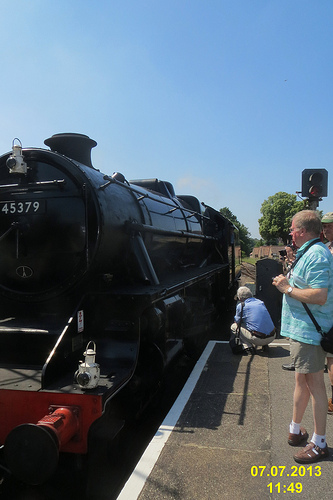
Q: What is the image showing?
A: It is showing a station.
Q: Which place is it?
A: It is a station.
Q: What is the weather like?
A: It is clear.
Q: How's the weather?
A: It is clear.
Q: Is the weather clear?
A: Yes, it is clear.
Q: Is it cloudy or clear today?
A: It is clear.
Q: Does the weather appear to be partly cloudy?
A: No, it is clear.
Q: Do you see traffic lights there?
A: Yes, there is a traffic light.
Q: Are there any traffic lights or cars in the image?
A: Yes, there is a traffic light.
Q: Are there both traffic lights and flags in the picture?
A: No, there is a traffic light but no flags.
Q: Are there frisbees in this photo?
A: No, there are no frisbees.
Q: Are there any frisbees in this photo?
A: No, there are no frisbees.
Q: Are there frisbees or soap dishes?
A: No, there are no frisbees or soap dishes.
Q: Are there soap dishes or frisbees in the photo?
A: No, there are no frisbees or soap dishes.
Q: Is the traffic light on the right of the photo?
A: Yes, the traffic light is on the right of the image.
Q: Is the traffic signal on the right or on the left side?
A: The traffic signal is on the right of the image.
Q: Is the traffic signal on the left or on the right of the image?
A: The traffic signal is on the right of the image.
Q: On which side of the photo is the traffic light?
A: The traffic light is on the right of the image.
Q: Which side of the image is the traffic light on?
A: The traffic light is on the right of the image.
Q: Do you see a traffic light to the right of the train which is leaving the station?
A: Yes, there is a traffic light to the right of the train.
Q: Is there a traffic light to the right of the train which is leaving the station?
A: Yes, there is a traffic light to the right of the train.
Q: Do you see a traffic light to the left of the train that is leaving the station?
A: No, the traffic light is to the right of the train.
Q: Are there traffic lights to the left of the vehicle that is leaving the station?
A: No, the traffic light is to the right of the train.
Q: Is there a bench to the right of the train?
A: No, there is a traffic light to the right of the train.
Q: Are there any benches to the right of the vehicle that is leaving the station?
A: No, there is a traffic light to the right of the train.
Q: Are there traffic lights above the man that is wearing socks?
A: Yes, there is a traffic light above the man.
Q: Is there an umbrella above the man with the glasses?
A: No, there is a traffic light above the man.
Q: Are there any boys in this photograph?
A: No, there are no boys.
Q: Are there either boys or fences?
A: No, there are no boys or fences.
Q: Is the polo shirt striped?
A: Yes, the polo shirt is striped.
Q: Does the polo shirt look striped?
A: Yes, the polo shirt is striped.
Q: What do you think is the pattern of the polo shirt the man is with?
A: The polo shirt is striped.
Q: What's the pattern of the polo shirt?
A: The polo shirt is striped.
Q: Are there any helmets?
A: No, there are no helmets.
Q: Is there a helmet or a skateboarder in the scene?
A: No, there are no helmets or skateboarders.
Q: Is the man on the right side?
A: Yes, the man is on the right of the image.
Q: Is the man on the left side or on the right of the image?
A: The man is on the right of the image.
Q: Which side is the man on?
A: The man is on the right of the image.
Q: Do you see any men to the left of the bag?
A: Yes, there is a man to the left of the bag.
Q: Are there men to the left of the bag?
A: Yes, there is a man to the left of the bag.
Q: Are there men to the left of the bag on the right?
A: Yes, there is a man to the left of the bag.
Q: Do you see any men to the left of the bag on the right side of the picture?
A: Yes, there is a man to the left of the bag.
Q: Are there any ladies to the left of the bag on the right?
A: No, there is a man to the left of the bag.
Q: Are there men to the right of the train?
A: Yes, there is a man to the right of the train.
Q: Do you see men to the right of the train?
A: Yes, there is a man to the right of the train.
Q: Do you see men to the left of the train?
A: No, the man is to the right of the train.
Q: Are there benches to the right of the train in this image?
A: No, there is a man to the right of the train.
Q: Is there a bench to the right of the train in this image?
A: No, there is a man to the right of the train.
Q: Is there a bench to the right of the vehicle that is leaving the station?
A: No, there is a man to the right of the train.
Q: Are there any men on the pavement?
A: Yes, there is a man on the pavement.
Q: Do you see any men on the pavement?
A: Yes, there is a man on the pavement.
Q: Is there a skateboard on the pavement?
A: No, there is a man on the pavement.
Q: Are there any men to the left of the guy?
A: Yes, there is a man to the left of the guy.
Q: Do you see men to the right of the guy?
A: No, the man is to the left of the guy.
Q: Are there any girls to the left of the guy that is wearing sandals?
A: No, there is a man to the left of the guy.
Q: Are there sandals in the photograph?
A: Yes, there are sandals.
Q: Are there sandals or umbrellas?
A: Yes, there are sandals.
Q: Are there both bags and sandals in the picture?
A: Yes, there are both sandals and a bag.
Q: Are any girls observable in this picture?
A: No, there are no girls.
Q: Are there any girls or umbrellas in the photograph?
A: No, there are no girls or umbrellas.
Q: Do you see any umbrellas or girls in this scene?
A: No, there are no girls or umbrellas.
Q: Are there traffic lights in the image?
A: Yes, there is a traffic light.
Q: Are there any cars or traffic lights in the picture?
A: Yes, there is a traffic light.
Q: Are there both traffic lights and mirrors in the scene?
A: No, there is a traffic light but no mirrors.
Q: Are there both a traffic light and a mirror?
A: No, there is a traffic light but no mirrors.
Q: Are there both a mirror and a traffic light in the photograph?
A: No, there is a traffic light but no mirrors.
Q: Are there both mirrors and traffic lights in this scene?
A: No, there is a traffic light but no mirrors.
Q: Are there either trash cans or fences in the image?
A: No, there are no fences or trash cans.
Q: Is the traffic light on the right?
A: Yes, the traffic light is on the right of the image.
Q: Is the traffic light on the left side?
A: No, the traffic light is on the right of the image.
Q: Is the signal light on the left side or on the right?
A: The signal light is on the right of the image.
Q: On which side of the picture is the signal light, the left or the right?
A: The signal light is on the right of the image.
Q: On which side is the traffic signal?
A: The traffic signal is on the right of the image.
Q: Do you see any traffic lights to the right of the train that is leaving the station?
A: Yes, there is a traffic light to the right of the train.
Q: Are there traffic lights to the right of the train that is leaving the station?
A: Yes, there is a traffic light to the right of the train.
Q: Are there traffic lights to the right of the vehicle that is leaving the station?
A: Yes, there is a traffic light to the right of the train.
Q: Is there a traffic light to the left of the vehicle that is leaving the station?
A: No, the traffic light is to the right of the train.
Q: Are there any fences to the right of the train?
A: No, there is a traffic light to the right of the train.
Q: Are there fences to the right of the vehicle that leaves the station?
A: No, there is a traffic light to the right of the train.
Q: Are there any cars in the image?
A: No, there are no cars.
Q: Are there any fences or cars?
A: No, there are no cars or fences.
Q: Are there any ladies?
A: No, there are no ladies.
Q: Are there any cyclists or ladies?
A: No, there are no ladies or cyclists.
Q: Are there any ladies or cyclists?
A: No, there are no ladies or cyclists.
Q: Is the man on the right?
A: Yes, the man is on the right of the image.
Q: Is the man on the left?
A: No, the man is on the right of the image.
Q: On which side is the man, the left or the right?
A: The man is on the right of the image.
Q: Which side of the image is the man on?
A: The man is on the right of the image.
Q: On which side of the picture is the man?
A: The man is on the right of the image.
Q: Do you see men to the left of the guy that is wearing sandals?
A: Yes, there is a man to the left of the guy.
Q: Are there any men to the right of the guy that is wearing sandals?
A: No, the man is to the left of the guy.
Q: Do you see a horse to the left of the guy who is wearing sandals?
A: No, there is a man to the left of the guy.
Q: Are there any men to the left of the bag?
A: Yes, there is a man to the left of the bag.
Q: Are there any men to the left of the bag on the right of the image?
A: Yes, there is a man to the left of the bag.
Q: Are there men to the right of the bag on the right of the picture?
A: No, the man is to the left of the bag.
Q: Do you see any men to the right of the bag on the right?
A: No, the man is to the left of the bag.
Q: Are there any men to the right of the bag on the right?
A: No, the man is to the left of the bag.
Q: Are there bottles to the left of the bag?
A: No, there is a man to the left of the bag.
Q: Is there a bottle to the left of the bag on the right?
A: No, there is a man to the left of the bag.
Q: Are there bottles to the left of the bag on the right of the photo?
A: No, there is a man to the left of the bag.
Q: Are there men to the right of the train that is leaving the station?
A: Yes, there is a man to the right of the train.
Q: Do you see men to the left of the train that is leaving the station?
A: No, the man is to the right of the train.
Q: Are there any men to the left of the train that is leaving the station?
A: No, the man is to the right of the train.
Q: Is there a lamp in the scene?
A: Yes, there is a lamp.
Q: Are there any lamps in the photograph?
A: Yes, there is a lamp.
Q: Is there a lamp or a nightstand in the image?
A: Yes, there is a lamp.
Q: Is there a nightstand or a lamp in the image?
A: Yes, there is a lamp.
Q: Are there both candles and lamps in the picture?
A: No, there is a lamp but no candles.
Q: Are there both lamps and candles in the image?
A: No, there is a lamp but no candles.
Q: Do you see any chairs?
A: No, there are no chairs.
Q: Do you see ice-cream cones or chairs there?
A: No, there are no chairs or ice-cream cones.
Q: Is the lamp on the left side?
A: Yes, the lamp is on the left of the image.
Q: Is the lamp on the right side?
A: No, the lamp is on the left of the image.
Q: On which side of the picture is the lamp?
A: The lamp is on the left of the image.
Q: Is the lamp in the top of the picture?
A: No, the lamp is in the bottom of the image.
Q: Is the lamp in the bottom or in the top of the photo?
A: The lamp is in the bottom of the image.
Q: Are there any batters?
A: No, there are no batters.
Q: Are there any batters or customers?
A: No, there are no batters or customers.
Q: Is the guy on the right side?
A: Yes, the guy is on the right of the image.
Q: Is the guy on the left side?
A: No, the guy is on the right of the image.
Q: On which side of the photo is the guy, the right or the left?
A: The guy is on the right of the image.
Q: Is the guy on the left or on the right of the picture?
A: The guy is on the right of the image.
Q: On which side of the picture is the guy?
A: The guy is on the right of the image.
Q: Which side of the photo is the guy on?
A: The guy is on the right of the image.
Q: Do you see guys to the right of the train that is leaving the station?
A: Yes, there is a guy to the right of the train.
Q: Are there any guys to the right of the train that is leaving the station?
A: Yes, there is a guy to the right of the train.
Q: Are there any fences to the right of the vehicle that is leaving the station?
A: No, there is a guy to the right of the train.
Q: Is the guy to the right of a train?
A: Yes, the guy is to the right of a train.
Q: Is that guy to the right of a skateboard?
A: No, the guy is to the right of a train.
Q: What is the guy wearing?
A: The guy is wearing sandals.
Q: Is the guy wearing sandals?
A: Yes, the guy is wearing sandals.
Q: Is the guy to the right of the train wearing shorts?
A: No, the guy is wearing sandals.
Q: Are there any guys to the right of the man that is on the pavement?
A: Yes, there is a guy to the right of the man.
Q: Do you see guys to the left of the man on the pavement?
A: No, the guy is to the right of the man.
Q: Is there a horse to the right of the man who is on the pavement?
A: No, there is a guy to the right of the man.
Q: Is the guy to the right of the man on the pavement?
A: Yes, the guy is to the right of the man.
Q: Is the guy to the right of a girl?
A: No, the guy is to the right of the man.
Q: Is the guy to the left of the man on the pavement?
A: No, the guy is to the right of the man.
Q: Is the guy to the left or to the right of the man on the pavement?
A: The guy is to the right of the man.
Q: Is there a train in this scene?
A: Yes, there is a train.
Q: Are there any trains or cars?
A: Yes, there is a train.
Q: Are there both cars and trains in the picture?
A: No, there is a train but no cars.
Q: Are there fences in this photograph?
A: No, there are no fences.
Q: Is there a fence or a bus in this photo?
A: No, there are no fences or buses.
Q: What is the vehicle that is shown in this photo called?
A: The vehicle is a train.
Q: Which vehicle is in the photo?
A: The vehicle is a train.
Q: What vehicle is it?
A: The vehicle is a train.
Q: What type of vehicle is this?
A: This is a train.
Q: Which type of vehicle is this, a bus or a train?
A: This is a train.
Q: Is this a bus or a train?
A: This is a train.